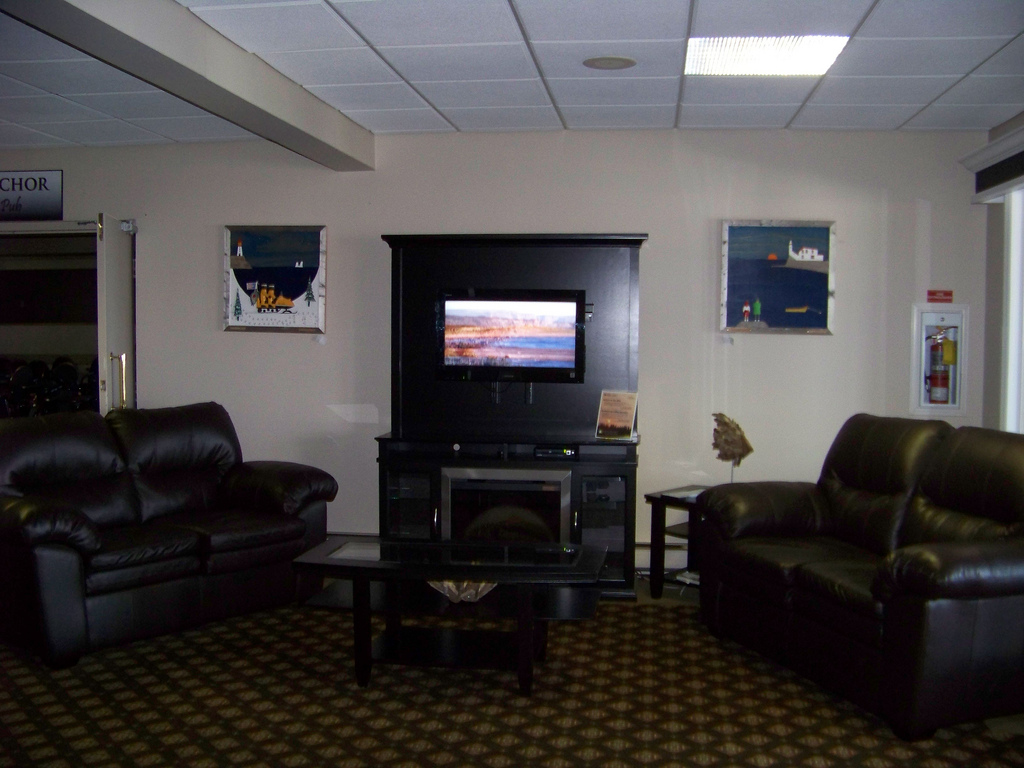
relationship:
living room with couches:
[0, 0, 1024, 768] [98, 369, 973, 648]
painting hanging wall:
[212, 205, 846, 359] [135, 160, 954, 580]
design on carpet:
[530, 717, 589, 750] [320, 590, 787, 763]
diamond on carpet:
[102, 663, 224, 752] [20, 637, 429, 763]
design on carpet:
[334, 717, 363, 743] [6, 559, 1022, 767]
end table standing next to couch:
[644, 485, 715, 601] [696, 414, 1024, 742]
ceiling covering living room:
[9, 3, 1021, 144] [3, 3, 993, 764]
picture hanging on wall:
[714, 217, 842, 341] [3, 128, 993, 565]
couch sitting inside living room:
[2, 401, 341, 672] [0, 0, 1024, 768]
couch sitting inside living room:
[696, 414, 1024, 742] [0, 0, 1024, 768]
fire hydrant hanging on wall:
[923, 322, 956, 407] [3, 128, 993, 565]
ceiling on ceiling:
[0, 0, 1024, 148] [9, 3, 1021, 144]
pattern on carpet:
[251, 672, 340, 742] [0, 568, 1024, 768]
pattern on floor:
[625, 629, 714, 707] [5, 565, 1023, 764]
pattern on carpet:
[476, 679, 572, 757] [0, 568, 1024, 768]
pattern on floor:
[426, 655, 649, 735] [38, 592, 959, 765]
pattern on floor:
[472, 668, 529, 721] [5, 565, 1023, 764]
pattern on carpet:
[351, 644, 449, 727] [0, 568, 1024, 768]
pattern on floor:
[651, 629, 697, 673] [5, 565, 1023, 764]